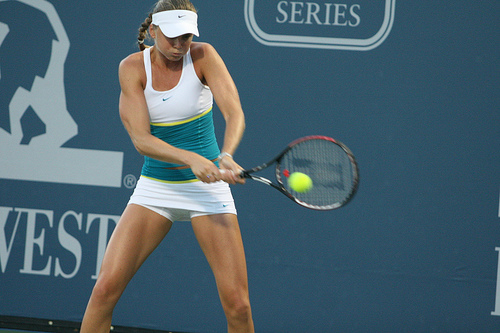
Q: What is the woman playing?
A: Tennis.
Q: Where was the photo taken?
A: Tennis court.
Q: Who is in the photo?
A: A lady.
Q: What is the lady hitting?
A: A ball.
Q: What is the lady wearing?
A: Tennis gear.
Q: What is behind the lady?
A: A wall.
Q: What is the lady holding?
A: A racket.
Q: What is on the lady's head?
A: A hat.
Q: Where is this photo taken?
A: A tennis court.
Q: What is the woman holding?
A: A tennis racket.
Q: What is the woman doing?
A: Playing tennis.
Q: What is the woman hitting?
A: Tennis ball.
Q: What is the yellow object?
A: Tennis ball.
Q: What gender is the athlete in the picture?
A: Female.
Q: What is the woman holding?
A: A tennis racquet.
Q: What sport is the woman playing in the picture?
A: Tennis.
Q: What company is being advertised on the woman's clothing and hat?
A: Nike.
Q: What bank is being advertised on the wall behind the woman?
A: Bank of the West.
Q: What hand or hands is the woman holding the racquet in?
A: Both hands.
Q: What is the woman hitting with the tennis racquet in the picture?
A: A tennis ball.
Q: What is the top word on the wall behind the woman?
A: Series.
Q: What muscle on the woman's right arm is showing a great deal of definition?
A: Triceps.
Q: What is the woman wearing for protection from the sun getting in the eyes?
A: A visor.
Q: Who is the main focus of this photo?
A: A person playing tennis.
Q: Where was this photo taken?
A: At a tennis tournament.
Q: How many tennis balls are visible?
A: One.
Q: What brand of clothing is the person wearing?
A: Nike.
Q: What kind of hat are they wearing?
A: A visor.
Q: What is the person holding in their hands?
A: A tennis racket.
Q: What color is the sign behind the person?
A: Blue and white.